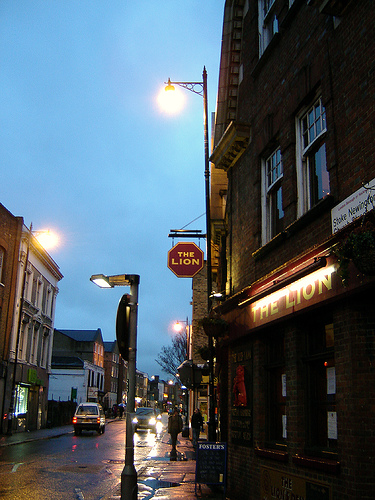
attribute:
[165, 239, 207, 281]
sign — eight sided, business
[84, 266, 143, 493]
light — street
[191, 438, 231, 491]
sign — chalk board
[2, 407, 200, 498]
street — two lane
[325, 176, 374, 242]
sign — white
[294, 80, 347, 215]
window — sliding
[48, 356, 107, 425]
building — white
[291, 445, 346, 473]
sill — outdoor window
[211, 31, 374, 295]
story — second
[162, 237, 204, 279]
sign — small, red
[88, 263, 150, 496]
light — street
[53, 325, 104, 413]
building — big, white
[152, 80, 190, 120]
light — on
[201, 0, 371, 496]
building — brown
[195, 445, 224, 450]
writing — white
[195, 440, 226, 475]
sign — black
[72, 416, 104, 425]
lights — red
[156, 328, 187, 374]
tree — bare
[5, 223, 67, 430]
street lamp — tall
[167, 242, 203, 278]
sign — red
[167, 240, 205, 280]
sign — octagon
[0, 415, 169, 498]
road — small, cement, wet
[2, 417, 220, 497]
ground — wet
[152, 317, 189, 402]
tree — bare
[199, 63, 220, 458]
post — tall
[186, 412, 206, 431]
sweater — black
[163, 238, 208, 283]
sign — octagon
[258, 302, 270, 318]
letter — white, print style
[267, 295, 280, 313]
letter — print style, white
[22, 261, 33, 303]
window — building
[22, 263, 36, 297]
window — building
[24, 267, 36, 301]
window — building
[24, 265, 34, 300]
window — building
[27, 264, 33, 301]
window — building